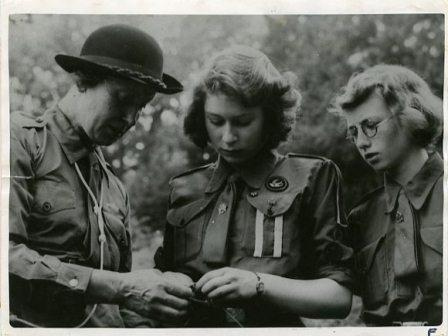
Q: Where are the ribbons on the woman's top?
A: On left.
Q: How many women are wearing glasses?
A: One woman.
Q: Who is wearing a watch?
A: Woman in the middle.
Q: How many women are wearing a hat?
A: One woman.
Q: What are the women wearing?
A: Uniforms.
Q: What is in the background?
A: Trees.